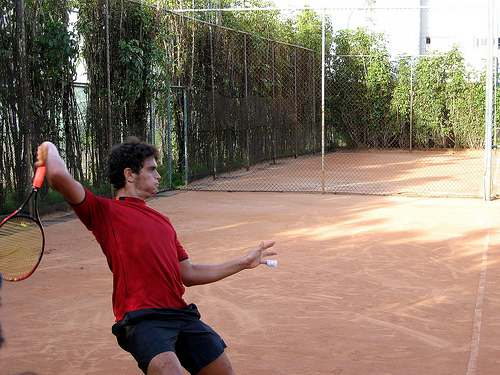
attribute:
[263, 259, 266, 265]
finger — wrapped, taped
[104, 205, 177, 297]
shirt — red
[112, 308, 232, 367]
shorts — blue, black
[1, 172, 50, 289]
tennis racket — red, black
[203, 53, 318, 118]
fence — metal, chainlink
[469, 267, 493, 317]
line — white, long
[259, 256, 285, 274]
splint — white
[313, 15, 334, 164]
pole — gray, long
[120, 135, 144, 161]
hair — black, curly, short, thick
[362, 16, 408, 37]
sky — white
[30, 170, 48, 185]
handle — red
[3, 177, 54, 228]
racket — black, red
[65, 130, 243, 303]
player — swinging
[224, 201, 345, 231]
court — orange, brown, red, white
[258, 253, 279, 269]
bandage — white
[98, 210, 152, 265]
tshirt — red